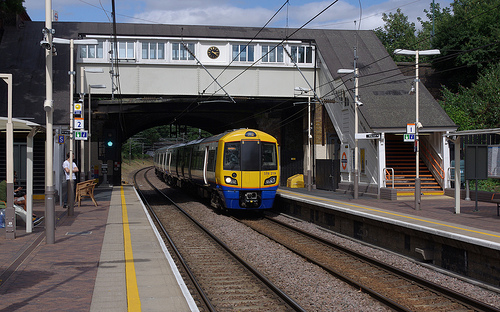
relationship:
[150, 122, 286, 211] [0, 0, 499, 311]
train arriving train station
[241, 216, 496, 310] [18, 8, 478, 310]
train rail on station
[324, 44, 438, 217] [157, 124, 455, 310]
pole facing railroad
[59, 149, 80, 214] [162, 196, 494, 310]
man standing beside tracks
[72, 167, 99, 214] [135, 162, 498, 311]
chairs sitting beside tracks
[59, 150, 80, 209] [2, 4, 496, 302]
man sitting at station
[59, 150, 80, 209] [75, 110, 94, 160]
man standing near train sign